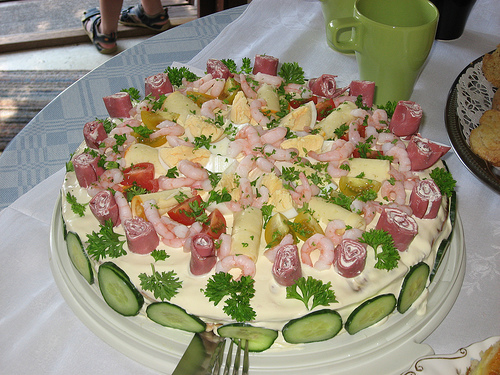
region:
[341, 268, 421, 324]
cucumber slices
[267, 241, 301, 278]
rolled meat with cream in it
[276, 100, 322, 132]
cut egg quarters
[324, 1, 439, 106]
green coffee mug on table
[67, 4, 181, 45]
feet wearing sandals standing in doorway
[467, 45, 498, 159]
cookies on a tray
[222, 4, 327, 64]
white table cloth on table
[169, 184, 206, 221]
cut up tomatoes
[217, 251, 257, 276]
cold cooked peeled shrimp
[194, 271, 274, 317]
leaves of parsley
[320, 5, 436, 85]
green mug on table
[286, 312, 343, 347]
green cucumber on cake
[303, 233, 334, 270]
shrimp on yellow cake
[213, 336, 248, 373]
four pronged silver fork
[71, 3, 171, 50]
blue sandals on a person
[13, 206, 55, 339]
white cloth on a table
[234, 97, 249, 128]
yellow and white egg on cake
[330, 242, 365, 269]
ham rollup on cake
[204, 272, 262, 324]
parsley leaves on cake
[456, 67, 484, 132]
white doily on silver plate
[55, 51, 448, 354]
a display of food on a tray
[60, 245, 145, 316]
cucumber slices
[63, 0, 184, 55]
person wearing black sandals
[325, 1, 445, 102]
a green cup on a table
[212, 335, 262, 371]
tip of a fork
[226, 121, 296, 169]
a bunch of shrimps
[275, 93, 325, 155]
boiled eggs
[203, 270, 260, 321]
a bunch of parsley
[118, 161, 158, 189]
tomatoes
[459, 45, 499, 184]
cookies on a white doily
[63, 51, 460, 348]
tray of random foods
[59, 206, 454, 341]
ring of cucumbers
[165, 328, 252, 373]
tip of knife and fork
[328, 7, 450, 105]
light green coffee cup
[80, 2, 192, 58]
feet in sandals of person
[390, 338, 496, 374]
ruffled edge of plate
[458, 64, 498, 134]
doily on plate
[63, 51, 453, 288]
ring of rolled ham slices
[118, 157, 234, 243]
slices of tomato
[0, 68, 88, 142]
striped rug on the floor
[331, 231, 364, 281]
sliced salami with cream cheese rolls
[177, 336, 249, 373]
stainless steel fork and butter knife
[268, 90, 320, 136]
piece of hard boiled egg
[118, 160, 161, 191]
wedge of grape tomoto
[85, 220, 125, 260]
parsley used for garnish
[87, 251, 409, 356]
thinly sliced cucumbers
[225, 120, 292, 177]
pink baby shrimp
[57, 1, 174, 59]
feet wearing black sandals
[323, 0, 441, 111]
lime green coffee cup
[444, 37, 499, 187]
plate of crackers on lace doily